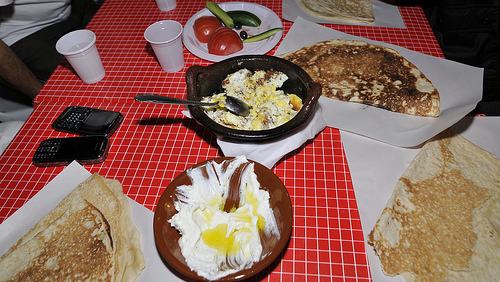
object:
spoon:
[133, 94, 250, 117]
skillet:
[182, 54, 324, 140]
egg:
[166, 155, 281, 282]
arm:
[0, 39, 46, 98]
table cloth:
[0, 100, 500, 282]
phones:
[32, 135, 110, 167]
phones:
[51, 105, 123, 138]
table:
[0, 100, 500, 282]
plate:
[152, 156, 293, 282]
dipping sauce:
[166, 155, 281, 282]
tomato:
[197, 25, 220, 44]